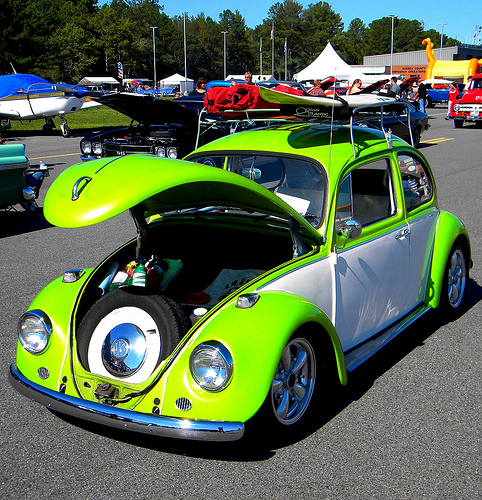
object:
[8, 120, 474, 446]
vehicle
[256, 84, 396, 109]
surfboard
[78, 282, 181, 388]
wheel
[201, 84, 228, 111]
bag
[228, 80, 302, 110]
bag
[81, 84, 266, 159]
car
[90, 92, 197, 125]
hood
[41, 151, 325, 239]
hood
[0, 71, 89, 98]
tarp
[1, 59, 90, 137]
plane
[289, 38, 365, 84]
tent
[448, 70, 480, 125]
truck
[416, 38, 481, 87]
house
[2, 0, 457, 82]
trees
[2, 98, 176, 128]
field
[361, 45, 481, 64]
building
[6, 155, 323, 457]
front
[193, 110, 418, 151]
rack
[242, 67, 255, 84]
man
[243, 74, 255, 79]
sunglasses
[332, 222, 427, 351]
door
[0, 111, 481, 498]
lot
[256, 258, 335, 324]
panel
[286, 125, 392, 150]
shadow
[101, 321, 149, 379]
hubcap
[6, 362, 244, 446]
bumper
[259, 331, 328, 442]
tire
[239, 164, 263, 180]
mirror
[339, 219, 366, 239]
mirror